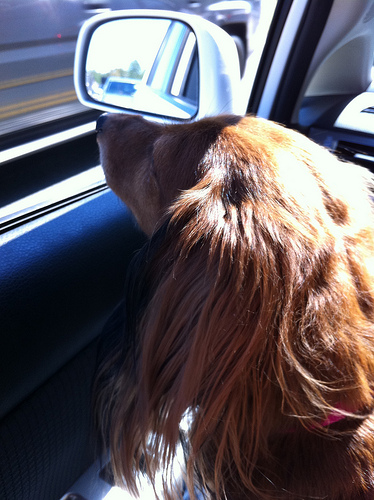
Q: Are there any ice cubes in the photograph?
A: No, there are no ice cubes.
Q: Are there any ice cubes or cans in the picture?
A: No, there are no ice cubes or cans.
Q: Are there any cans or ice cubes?
A: No, there are no ice cubes or cans.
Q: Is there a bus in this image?
A: No, there are no buses.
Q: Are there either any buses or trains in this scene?
A: No, there are no buses or trains.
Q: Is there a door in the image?
A: Yes, there is a door.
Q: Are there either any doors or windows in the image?
A: Yes, there is a door.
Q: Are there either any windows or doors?
A: Yes, there is a door.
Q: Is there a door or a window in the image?
A: Yes, there is a door.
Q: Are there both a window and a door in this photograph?
A: Yes, there are both a door and a window.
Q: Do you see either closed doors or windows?
A: Yes, there is a closed door.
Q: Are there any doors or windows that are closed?
A: Yes, the door is closed.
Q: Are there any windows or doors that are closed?
A: Yes, the door is closed.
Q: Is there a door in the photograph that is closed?
A: Yes, there is a closed door.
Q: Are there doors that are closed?
A: Yes, there is a door that is closed.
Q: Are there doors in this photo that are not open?
A: Yes, there is an closed door.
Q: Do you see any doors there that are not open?
A: Yes, there is an closed door.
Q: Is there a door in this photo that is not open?
A: Yes, there is an closed door.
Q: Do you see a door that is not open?
A: Yes, there is an closed door.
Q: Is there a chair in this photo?
A: No, there are no chairs.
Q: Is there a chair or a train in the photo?
A: No, there are no chairs or trains.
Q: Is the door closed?
A: Yes, the door is closed.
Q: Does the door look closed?
A: Yes, the door is closed.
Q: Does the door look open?
A: No, the door is closed.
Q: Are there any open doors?
A: No, there is a door but it is closed.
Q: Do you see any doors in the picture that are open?
A: No, there is a door but it is closed.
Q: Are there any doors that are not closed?
A: No, there is a door but it is closed.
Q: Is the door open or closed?
A: The door is closed.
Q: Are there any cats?
A: No, there are no cats.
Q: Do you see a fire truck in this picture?
A: No, there are no fire trucks.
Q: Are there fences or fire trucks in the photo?
A: No, there are no fire trucks or fences.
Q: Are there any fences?
A: No, there are no fences.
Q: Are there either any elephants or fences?
A: No, there are no fences or elephants.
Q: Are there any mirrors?
A: Yes, there is a mirror.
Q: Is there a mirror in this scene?
A: Yes, there is a mirror.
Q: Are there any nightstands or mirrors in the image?
A: Yes, there is a mirror.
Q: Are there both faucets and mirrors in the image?
A: No, there is a mirror but no faucets.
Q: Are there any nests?
A: No, there are no nests.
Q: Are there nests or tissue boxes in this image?
A: No, there are no nests or tissue boxes.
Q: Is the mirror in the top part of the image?
A: Yes, the mirror is in the top of the image.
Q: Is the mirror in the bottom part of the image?
A: No, the mirror is in the top of the image.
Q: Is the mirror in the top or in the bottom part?
A: The mirror is in the top of the image.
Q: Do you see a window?
A: Yes, there is a window.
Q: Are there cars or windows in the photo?
A: Yes, there is a window.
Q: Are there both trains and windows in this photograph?
A: No, there is a window but no trains.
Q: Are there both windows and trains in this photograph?
A: No, there is a window but no trains.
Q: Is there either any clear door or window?
A: Yes, there is a clear window.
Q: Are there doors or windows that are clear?
A: Yes, the window is clear.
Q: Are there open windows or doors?
A: Yes, there is an open window.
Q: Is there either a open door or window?
A: Yes, there is an open window.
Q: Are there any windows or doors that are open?
A: Yes, the window is open.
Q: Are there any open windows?
A: Yes, there is an open window.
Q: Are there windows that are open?
A: Yes, there is a window that is open.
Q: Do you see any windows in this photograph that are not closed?
A: Yes, there is a open window.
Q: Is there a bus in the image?
A: No, there are no buses.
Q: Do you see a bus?
A: No, there are no buses.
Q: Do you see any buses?
A: No, there are no buses.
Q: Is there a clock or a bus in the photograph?
A: No, there are no buses or clocks.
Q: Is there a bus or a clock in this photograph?
A: No, there are no buses or clocks.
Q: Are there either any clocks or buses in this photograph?
A: No, there are no buses or clocks.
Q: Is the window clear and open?
A: Yes, the window is clear and open.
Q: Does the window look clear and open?
A: Yes, the window is clear and open.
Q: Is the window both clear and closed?
A: No, the window is clear but open.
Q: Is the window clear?
A: Yes, the window is clear.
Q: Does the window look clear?
A: Yes, the window is clear.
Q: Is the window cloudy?
A: No, the window is clear.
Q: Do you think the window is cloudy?
A: No, the window is clear.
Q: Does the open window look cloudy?
A: No, the window is clear.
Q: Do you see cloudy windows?
A: No, there is a window but it is clear.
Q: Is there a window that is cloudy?
A: No, there is a window but it is clear.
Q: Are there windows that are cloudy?
A: No, there is a window but it is clear.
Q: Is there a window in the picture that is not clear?
A: No, there is a window but it is clear.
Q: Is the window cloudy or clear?
A: The window is clear.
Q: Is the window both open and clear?
A: Yes, the window is open and clear.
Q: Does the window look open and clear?
A: Yes, the window is open and clear.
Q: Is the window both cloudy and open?
A: No, the window is open but clear.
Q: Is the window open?
A: Yes, the window is open.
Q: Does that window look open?
A: Yes, the window is open.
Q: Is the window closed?
A: No, the window is open.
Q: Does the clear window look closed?
A: No, the window is open.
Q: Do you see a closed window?
A: No, there is a window but it is open.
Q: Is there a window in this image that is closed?
A: No, there is a window but it is open.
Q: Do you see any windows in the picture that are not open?
A: No, there is a window but it is open.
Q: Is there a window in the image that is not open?
A: No, there is a window but it is open.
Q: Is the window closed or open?
A: The window is open.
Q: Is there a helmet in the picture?
A: No, there are no helmets.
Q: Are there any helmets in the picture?
A: No, there are no helmets.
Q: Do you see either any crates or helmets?
A: No, there are no helmets or crates.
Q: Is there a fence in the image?
A: No, there are no fences.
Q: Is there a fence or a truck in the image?
A: No, there are no fences or trucks.